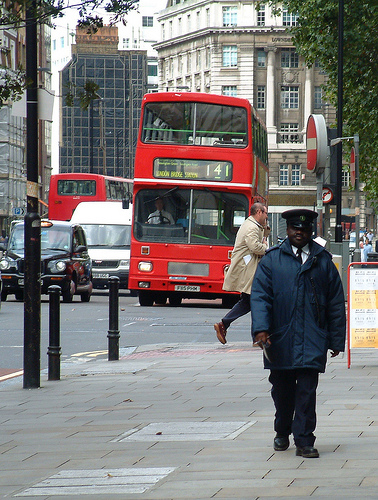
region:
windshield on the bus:
[144, 101, 247, 146]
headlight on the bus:
[135, 261, 151, 270]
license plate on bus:
[174, 282, 201, 293]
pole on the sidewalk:
[105, 273, 121, 359]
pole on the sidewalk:
[47, 286, 62, 379]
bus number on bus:
[154, 156, 233, 179]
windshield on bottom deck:
[136, 183, 243, 242]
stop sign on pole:
[299, 113, 324, 175]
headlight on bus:
[54, 261, 65, 271]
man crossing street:
[216, 199, 267, 343]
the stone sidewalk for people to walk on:
[3, 344, 374, 497]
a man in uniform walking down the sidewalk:
[248, 207, 347, 456]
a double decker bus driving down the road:
[122, 89, 269, 303]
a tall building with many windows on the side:
[157, 2, 353, 236]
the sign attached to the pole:
[299, 115, 327, 175]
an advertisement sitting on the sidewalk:
[344, 259, 377, 367]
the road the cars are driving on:
[5, 288, 249, 350]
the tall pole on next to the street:
[18, 4, 45, 386]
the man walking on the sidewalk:
[210, 200, 265, 343]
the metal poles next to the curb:
[48, 276, 120, 368]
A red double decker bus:
[124, 87, 270, 314]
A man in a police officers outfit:
[248, 206, 348, 463]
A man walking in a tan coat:
[212, 200, 271, 350]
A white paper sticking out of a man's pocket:
[242, 253, 251, 265]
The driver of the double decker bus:
[142, 197, 176, 225]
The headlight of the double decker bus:
[137, 261, 153, 271]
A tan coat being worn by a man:
[219, 212, 268, 295]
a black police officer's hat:
[277, 207, 319, 230]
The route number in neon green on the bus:
[202, 161, 231, 179]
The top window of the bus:
[138, 97, 251, 151]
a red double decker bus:
[125, 82, 241, 298]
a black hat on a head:
[285, 207, 310, 226]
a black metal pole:
[104, 272, 127, 356]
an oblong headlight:
[132, 253, 156, 272]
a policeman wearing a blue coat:
[250, 204, 355, 461]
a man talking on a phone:
[215, 200, 269, 355]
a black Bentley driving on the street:
[2, 215, 93, 304]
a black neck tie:
[296, 250, 301, 259]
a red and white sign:
[301, 112, 325, 174]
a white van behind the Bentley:
[80, 201, 129, 280]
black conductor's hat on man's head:
[276, 205, 326, 233]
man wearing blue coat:
[242, 244, 345, 373]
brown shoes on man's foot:
[208, 321, 233, 341]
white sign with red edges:
[336, 255, 371, 366]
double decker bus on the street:
[118, 81, 257, 297]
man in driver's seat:
[137, 193, 174, 235]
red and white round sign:
[296, 115, 338, 177]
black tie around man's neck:
[286, 244, 317, 263]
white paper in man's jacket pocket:
[238, 246, 259, 269]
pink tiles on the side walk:
[128, 345, 227, 362]